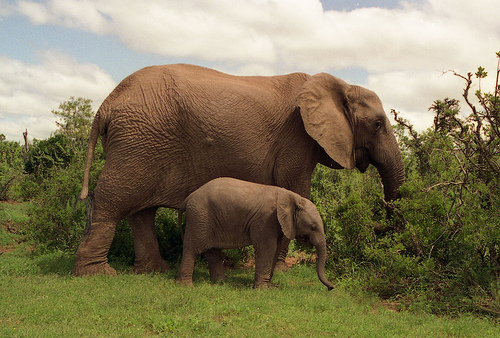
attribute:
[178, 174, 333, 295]
elephant — together, baby, brown, standing, facing right, small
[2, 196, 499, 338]
grass — green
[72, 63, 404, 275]
elephant — adult, large, bump, brown, mother, standing, facing right, together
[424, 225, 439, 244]
leaves — green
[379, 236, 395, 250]
leaves — green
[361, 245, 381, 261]
leaves — green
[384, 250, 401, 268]
leaves — green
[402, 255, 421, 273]
leaves — green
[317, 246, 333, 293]
trunk — small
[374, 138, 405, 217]
trunk — large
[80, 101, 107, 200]
tail — thin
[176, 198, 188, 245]
tail — thin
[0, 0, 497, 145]
sky — blue, cloudy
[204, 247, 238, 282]
leg — hind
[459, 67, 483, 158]
branches — bare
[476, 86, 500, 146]
branches — bare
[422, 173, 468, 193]
branches — bare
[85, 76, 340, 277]
skin — wrinkle